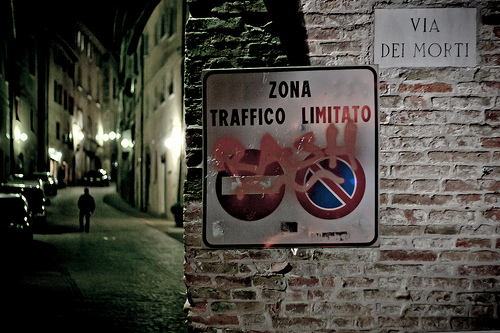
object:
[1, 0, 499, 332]
street scene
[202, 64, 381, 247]
traffic sign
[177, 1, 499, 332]
wall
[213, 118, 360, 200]
graffiti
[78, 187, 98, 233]
person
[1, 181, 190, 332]
street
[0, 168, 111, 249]
automobiles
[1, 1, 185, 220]
buildings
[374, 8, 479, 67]
name plaque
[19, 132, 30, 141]
light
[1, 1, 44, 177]
building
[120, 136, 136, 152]
window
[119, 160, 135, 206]
archway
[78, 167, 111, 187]
car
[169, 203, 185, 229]
fire hydrant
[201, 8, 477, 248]
signs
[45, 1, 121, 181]
building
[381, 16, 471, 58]
via dei morti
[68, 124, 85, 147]
light